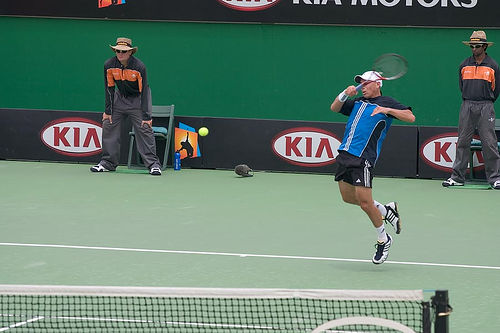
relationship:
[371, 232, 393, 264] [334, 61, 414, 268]
feet on person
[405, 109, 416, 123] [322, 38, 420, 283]
elbow on athlete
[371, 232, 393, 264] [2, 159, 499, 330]
feet on tennis court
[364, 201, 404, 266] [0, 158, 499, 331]
feet on court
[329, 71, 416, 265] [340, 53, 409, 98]
athlete swinging tennis racket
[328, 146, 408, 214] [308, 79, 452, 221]
shorts on person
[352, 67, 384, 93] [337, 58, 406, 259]
cap on man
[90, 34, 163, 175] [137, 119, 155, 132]
man on knee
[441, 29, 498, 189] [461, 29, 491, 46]
man wearing hat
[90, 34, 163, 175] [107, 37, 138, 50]
man wearing hat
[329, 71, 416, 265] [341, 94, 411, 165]
athlete wearing shirt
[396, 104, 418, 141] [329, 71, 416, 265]
elbow of a athlete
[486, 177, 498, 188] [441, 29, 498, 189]
foot on man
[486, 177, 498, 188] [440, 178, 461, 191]
foot on foot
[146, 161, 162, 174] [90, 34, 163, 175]
foot on man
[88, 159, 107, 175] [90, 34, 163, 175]
foot on man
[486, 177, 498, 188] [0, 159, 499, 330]
foot on ground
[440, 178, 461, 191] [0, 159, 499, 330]
foot on ground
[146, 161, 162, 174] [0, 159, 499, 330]
foot on ground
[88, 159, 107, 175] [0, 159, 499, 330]
foot on ground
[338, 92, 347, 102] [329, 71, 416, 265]
wrist band on athlete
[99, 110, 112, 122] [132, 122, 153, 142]
hand on knee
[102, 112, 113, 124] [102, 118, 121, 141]
hand on knee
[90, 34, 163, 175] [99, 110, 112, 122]
man has hand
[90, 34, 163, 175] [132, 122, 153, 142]
man has knee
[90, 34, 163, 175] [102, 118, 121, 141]
man has knee